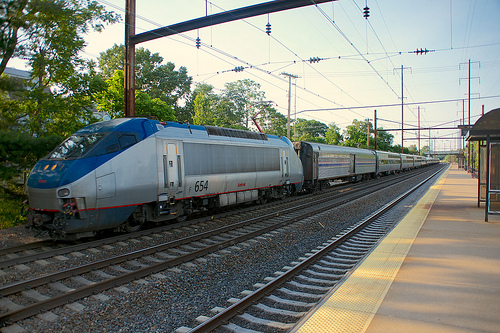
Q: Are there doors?
A: Yes, there is a door.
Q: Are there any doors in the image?
A: Yes, there is a door.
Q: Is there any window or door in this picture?
A: Yes, there is a door.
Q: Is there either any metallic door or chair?
A: Yes, there is a metal door.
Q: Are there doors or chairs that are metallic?
A: Yes, the door is metallic.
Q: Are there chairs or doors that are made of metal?
A: Yes, the door is made of metal.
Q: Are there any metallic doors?
A: Yes, there is a metal door.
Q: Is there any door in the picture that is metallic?
A: Yes, there is a door that is metallic.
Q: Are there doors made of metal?
A: Yes, there is a door that is made of metal.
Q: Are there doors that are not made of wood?
A: Yes, there is a door that is made of metal.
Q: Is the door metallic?
A: Yes, the door is metallic.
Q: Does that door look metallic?
A: Yes, the door is metallic.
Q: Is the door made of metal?
A: Yes, the door is made of metal.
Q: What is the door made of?
A: The door is made of metal.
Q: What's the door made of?
A: The door is made of metal.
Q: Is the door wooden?
A: No, the door is metallic.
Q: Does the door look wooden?
A: No, the door is metallic.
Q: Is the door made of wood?
A: No, the door is made of metal.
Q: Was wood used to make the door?
A: No, the door is made of metal.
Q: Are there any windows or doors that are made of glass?
A: No, there is a door but it is made of metal.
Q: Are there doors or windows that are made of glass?
A: No, there is a door but it is made of metal.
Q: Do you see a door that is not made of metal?
A: No, there is a door but it is made of metal.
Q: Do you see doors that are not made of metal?
A: No, there is a door but it is made of metal.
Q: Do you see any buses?
A: No, there are no buses.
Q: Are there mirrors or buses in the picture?
A: No, there are no buses or mirrors.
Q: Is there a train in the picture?
A: Yes, there is a train.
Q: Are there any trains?
A: Yes, there is a train.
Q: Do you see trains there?
A: Yes, there is a train.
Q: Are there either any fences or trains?
A: Yes, there is a train.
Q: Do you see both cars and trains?
A: Yes, there are both a train and a car.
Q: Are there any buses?
A: No, there are no buses.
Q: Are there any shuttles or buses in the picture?
A: No, there are no buses or shuttles.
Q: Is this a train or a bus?
A: This is a train.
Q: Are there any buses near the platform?
A: No, there is a train near the platform.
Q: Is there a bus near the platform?
A: No, there is a train near the platform.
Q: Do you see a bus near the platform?
A: No, there is a train near the platform.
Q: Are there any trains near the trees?
A: Yes, there is a train near the trees.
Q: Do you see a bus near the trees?
A: No, there is a train near the trees.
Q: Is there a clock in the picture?
A: No, there are no clocks.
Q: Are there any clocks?
A: No, there are no clocks.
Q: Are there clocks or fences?
A: No, there are no clocks or fences.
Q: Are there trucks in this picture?
A: No, there are no trucks.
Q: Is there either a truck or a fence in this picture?
A: No, there are no trucks or fences.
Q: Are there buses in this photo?
A: No, there are no buses.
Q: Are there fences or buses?
A: No, there are no buses or fences.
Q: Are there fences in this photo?
A: No, there are no fences.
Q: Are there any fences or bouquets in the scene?
A: No, there are no fences or bouquets.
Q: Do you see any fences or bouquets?
A: No, there are no fences or bouquets.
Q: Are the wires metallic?
A: Yes, the wires are metallic.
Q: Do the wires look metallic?
A: Yes, the wires are metallic.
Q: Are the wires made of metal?
A: Yes, the wires are made of metal.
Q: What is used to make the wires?
A: The wires are made of metal.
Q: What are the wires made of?
A: The wires are made of metal.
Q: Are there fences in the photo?
A: No, there are no fences.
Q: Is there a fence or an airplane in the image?
A: No, there are no fences or airplanes.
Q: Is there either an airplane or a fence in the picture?
A: No, there are no fences or airplanes.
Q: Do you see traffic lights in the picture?
A: No, there are no traffic lights.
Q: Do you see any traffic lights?
A: No, there are no traffic lights.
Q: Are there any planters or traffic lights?
A: No, there are no traffic lights or planters.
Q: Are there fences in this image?
A: No, there are no fences.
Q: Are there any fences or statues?
A: No, there are no fences or statues.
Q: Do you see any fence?
A: No, there are no fences.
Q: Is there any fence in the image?
A: No, there are no fences.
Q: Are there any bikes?
A: No, there are no bikes.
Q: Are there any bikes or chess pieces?
A: No, there are no bikes or chess pieces.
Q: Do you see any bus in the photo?
A: No, there are no buses.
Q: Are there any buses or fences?
A: No, there are no buses or fences.